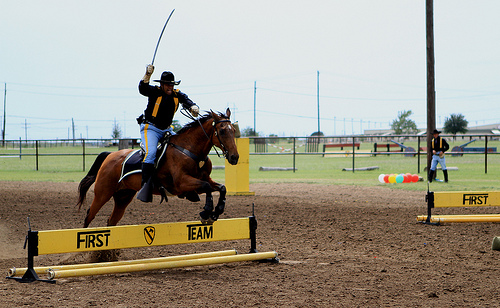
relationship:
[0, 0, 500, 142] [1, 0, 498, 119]
cloud in sky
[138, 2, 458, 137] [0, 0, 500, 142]
cloud in cloud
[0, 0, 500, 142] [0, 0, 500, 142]
cloud in cloud